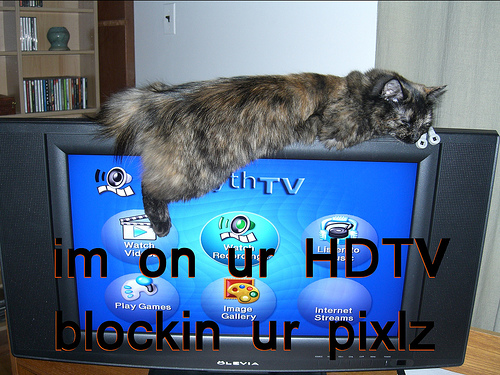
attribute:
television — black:
[2, 117, 498, 366]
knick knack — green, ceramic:
[45, 24, 72, 52]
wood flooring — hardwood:
[0, 322, 497, 373]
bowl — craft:
[22, 15, 96, 70]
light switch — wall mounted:
[158, 1, 179, 36]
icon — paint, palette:
[225, 282, 259, 302]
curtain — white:
[367, 0, 497, 149]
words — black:
[52, 235, 452, 352]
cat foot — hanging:
[137, 183, 177, 243]